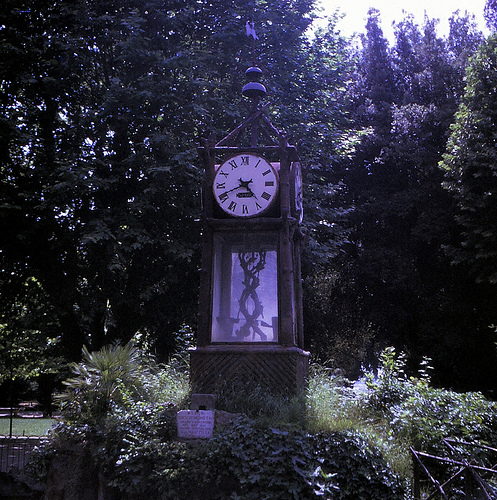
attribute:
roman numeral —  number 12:
[234, 154, 253, 170]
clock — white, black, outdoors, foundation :
[206, 149, 284, 219]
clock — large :
[215, 151, 278, 217]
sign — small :
[141, 397, 229, 447]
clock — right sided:
[191, 20, 311, 424]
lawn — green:
[7, 415, 51, 435]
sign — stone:
[159, 391, 248, 470]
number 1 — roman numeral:
[253, 158, 260, 168]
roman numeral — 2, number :
[258, 166, 285, 179]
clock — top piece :
[199, 129, 302, 221]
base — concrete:
[184, 350, 313, 423]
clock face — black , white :
[212, 152, 285, 218]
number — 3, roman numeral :
[263, 176, 285, 184]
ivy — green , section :
[93, 404, 401, 497]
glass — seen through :
[212, 249, 279, 340]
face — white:
[212, 153, 279, 218]